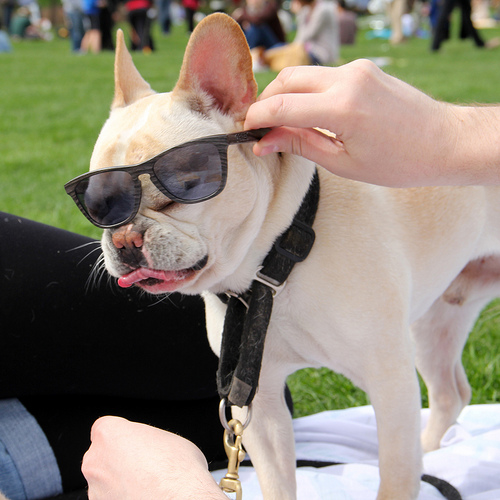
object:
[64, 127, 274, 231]
sunglasses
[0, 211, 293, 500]
person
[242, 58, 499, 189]
right hand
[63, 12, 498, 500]
dog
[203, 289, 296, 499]
front right leg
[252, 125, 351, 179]
thumb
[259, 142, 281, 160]
thumbnail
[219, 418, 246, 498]
clasp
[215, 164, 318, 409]
dog collar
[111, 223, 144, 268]
nose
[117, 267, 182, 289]
tongue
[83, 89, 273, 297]
face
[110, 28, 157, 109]
right ear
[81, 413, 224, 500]
left hand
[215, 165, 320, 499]
dog leash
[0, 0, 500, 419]
grass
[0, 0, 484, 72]
group of people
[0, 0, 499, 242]
background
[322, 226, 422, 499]
front left leg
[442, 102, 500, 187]
wrist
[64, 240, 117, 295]
group of whiskers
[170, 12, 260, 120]
left ear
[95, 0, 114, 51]
person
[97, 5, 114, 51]
pants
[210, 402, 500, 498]
blanket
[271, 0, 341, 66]
person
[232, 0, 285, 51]
person